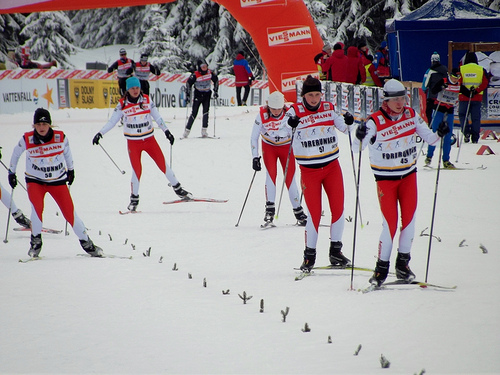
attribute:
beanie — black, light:
[296, 67, 320, 95]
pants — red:
[295, 157, 361, 278]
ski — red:
[194, 189, 231, 214]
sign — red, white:
[241, 13, 344, 124]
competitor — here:
[107, 70, 208, 230]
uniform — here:
[27, 107, 96, 265]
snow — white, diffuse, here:
[209, 196, 258, 262]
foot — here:
[256, 203, 286, 235]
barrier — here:
[4, 59, 134, 112]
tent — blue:
[383, 22, 474, 116]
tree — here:
[137, 3, 271, 82]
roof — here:
[395, 6, 486, 42]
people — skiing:
[62, 33, 485, 288]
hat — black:
[298, 76, 323, 97]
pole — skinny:
[89, 128, 141, 171]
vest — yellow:
[460, 65, 483, 102]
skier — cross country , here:
[181, 44, 222, 148]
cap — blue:
[115, 74, 143, 91]